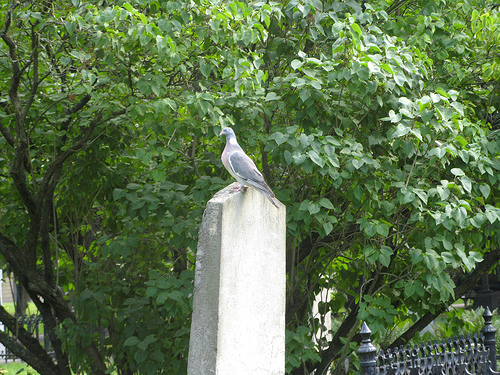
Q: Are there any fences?
A: Yes, there is a fence.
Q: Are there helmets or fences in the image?
A: Yes, there is a fence.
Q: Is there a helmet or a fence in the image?
A: Yes, there is a fence.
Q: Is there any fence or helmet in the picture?
A: Yes, there is a fence.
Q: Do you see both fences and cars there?
A: No, there is a fence but no cars.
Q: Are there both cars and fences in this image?
A: No, there is a fence but no cars.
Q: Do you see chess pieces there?
A: No, there are no chess pieces.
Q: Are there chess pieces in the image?
A: No, there are no chess pieces.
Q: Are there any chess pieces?
A: No, there are no chess pieces.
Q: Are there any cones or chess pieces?
A: No, there are no chess pieces or cones.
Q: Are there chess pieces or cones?
A: No, there are no chess pieces or cones.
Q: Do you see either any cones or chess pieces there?
A: No, there are no chess pieces or cones.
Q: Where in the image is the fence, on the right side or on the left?
A: The fence is on the right of the image.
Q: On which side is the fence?
A: The fence is on the right of the image.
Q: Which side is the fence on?
A: The fence is on the right of the image.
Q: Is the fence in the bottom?
A: Yes, the fence is in the bottom of the image.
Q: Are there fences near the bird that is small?
A: Yes, there is a fence near the bird.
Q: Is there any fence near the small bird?
A: Yes, there is a fence near the bird.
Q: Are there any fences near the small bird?
A: Yes, there is a fence near the bird.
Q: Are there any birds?
A: Yes, there is a bird.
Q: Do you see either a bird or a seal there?
A: Yes, there is a bird.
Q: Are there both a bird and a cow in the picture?
A: No, there is a bird but no cows.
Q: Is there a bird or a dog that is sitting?
A: Yes, the bird is sitting.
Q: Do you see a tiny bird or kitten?
A: Yes, there is a tiny bird.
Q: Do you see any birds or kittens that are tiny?
A: Yes, the bird is tiny.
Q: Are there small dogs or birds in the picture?
A: Yes, there is a small bird.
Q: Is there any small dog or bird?
A: Yes, there is a small bird.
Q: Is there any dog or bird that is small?
A: Yes, the bird is small.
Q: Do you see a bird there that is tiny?
A: Yes, there is a tiny bird.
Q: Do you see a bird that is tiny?
A: Yes, there is a bird that is tiny.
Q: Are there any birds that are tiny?
A: Yes, there is a bird that is tiny.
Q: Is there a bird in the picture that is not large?
A: Yes, there is a tiny bird.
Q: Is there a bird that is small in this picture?
A: Yes, there is a small bird.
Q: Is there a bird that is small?
A: Yes, there is a bird that is small.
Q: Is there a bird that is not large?
A: Yes, there is a small bird.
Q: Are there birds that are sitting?
A: Yes, there is a bird that is sitting.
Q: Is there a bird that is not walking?
A: Yes, there is a bird that is sitting.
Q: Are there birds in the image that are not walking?
A: Yes, there is a bird that is sitting.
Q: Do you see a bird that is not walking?
A: Yes, there is a bird that is sitting .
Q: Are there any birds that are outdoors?
A: Yes, there is a bird that is outdoors.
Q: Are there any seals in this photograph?
A: No, there are no seals.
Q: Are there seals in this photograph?
A: No, there are no seals.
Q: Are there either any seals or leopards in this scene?
A: No, there are no seals or leopards.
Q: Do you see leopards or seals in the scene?
A: No, there are no seals or leopards.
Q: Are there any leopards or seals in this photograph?
A: No, there are no seals or leopards.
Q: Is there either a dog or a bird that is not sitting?
A: No, there is a bird but it is sitting.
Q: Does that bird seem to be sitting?
A: Yes, the bird is sitting.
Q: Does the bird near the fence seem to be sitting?
A: Yes, the bird is sitting.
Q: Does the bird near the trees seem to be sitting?
A: Yes, the bird is sitting.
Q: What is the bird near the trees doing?
A: The bird is sitting.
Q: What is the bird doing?
A: The bird is sitting.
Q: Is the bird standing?
A: No, the bird is sitting.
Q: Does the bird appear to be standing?
A: No, the bird is sitting.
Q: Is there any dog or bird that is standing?
A: No, there is a bird but it is sitting.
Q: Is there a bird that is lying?
A: No, there is a bird but it is sitting.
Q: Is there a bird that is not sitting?
A: No, there is a bird but it is sitting.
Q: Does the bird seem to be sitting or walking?
A: The bird is sitting.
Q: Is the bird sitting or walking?
A: The bird is sitting.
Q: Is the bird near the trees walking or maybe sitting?
A: The bird is sitting.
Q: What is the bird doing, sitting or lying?
A: The bird is sitting.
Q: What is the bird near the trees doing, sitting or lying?
A: The bird is sitting.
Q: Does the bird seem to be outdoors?
A: Yes, the bird is outdoors.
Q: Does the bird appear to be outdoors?
A: Yes, the bird is outdoors.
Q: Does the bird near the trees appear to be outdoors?
A: Yes, the bird is outdoors.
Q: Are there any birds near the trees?
A: Yes, there is a bird near the trees.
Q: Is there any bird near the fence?
A: Yes, there is a bird near the fence.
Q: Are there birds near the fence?
A: Yes, there is a bird near the fence.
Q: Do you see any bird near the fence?
A: Yes, there is a bird near the fence.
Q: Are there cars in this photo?
A: No, there are no cars.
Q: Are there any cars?
A: No, there are no cars.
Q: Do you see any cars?
A: No, there are no cars.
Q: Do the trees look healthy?
A: Yes, the trees are healthy.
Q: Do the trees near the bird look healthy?
A: Yes, the trees are healthy.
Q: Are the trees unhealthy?
A: No, the trees are healthy.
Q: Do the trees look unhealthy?
A: No, the trees are healthy.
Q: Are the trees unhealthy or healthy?
A: The trees are healthy.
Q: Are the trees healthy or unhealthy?
A: The trees are healthy.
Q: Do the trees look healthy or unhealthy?
A: The trees are healthy.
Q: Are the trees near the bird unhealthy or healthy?
A: The trees are healthy.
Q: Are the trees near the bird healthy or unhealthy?
A: The trees are healthy.